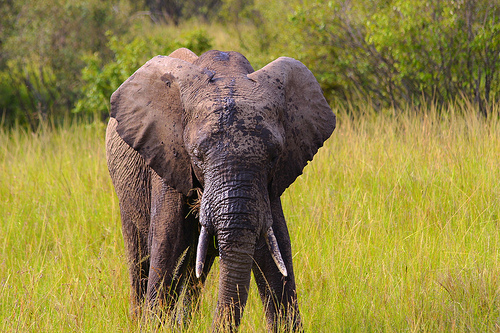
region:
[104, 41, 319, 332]
a baby elephant standing in the forest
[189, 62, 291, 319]
a baby elephant with mud on its face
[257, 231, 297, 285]
the white horns of an elephant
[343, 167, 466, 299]
the green grass in the forest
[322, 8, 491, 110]
the bunch of green trees in the forest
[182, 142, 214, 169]
the eyes of an elephant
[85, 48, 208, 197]
the long ears of an elephant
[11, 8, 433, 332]
a baby elephant standing in the forest with mud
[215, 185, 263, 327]
the trunk of the elephant with black mud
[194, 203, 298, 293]
the tusks of an elephant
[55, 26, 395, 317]
elephant surrounded by tall grass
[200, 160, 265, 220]
blackened and dried trunk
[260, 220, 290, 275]
black marks and lines along tusk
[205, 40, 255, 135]
black markings on head and back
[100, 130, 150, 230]
deep wrinkles on body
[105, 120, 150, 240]
sagging skin along side of body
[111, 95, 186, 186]
darker edges along ear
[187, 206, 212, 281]
short and black tusk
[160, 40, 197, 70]
hump behind ear and head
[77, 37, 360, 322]
tired and dark elephant walking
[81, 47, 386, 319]
An old elephant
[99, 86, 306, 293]
Elephant eating the grass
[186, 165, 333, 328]
The elephant has tusk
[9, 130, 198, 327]
Very tall grass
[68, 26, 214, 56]
Shrubs behind the elephant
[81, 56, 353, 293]
The elephant is covered with mud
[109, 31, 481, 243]
Large male elephant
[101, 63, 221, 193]
Elephant in the wild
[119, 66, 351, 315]
Elephant grazing in the field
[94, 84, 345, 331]
Elephant walking through the grass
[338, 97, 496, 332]
Tall lime green grass.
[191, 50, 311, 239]
Mud on the elephant.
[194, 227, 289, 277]
The two elephant tusks.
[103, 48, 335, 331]
The brown elephant standing.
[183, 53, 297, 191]
The elephant looking down.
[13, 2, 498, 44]
Trees in the background.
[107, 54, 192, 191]
The elephant's large ear.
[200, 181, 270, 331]
The trunk of the elephant.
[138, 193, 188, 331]
The leg of the elephant.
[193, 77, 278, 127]
The forehead of the elephant.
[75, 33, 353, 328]
Elephant with water splashed on its skin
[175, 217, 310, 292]
Two elephant tusks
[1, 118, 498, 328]
Field with tall grass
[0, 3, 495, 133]
Trees and bushes with green leaves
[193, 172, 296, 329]
Elephant trunk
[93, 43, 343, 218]
Elephant ears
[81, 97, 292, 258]
Wet and wrinkled elephant skin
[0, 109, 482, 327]
Green and brown grass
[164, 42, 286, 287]
Water splashed on elephant skin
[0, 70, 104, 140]
Shadow in the underbrush